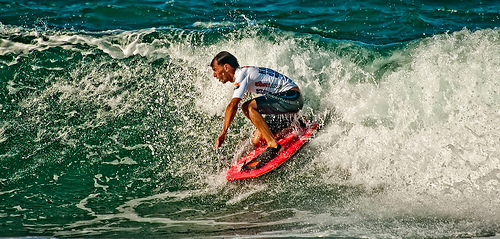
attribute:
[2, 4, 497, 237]
water — splashing, blue, greenish blue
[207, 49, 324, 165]
man — wet, crouched down, surfing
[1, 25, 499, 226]
wave — big, white, green, foamy, splashing, white capped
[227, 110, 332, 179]
surfboard — red, edged, partial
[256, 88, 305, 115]
shorts — blue, black, partial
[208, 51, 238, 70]
hair — dark, brown, short, black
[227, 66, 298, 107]
top — white, partial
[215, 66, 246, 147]
arm — in front, partial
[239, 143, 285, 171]
flipper — black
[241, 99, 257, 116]
knee — partial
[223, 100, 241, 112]
elbow — partial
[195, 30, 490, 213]
foam — white